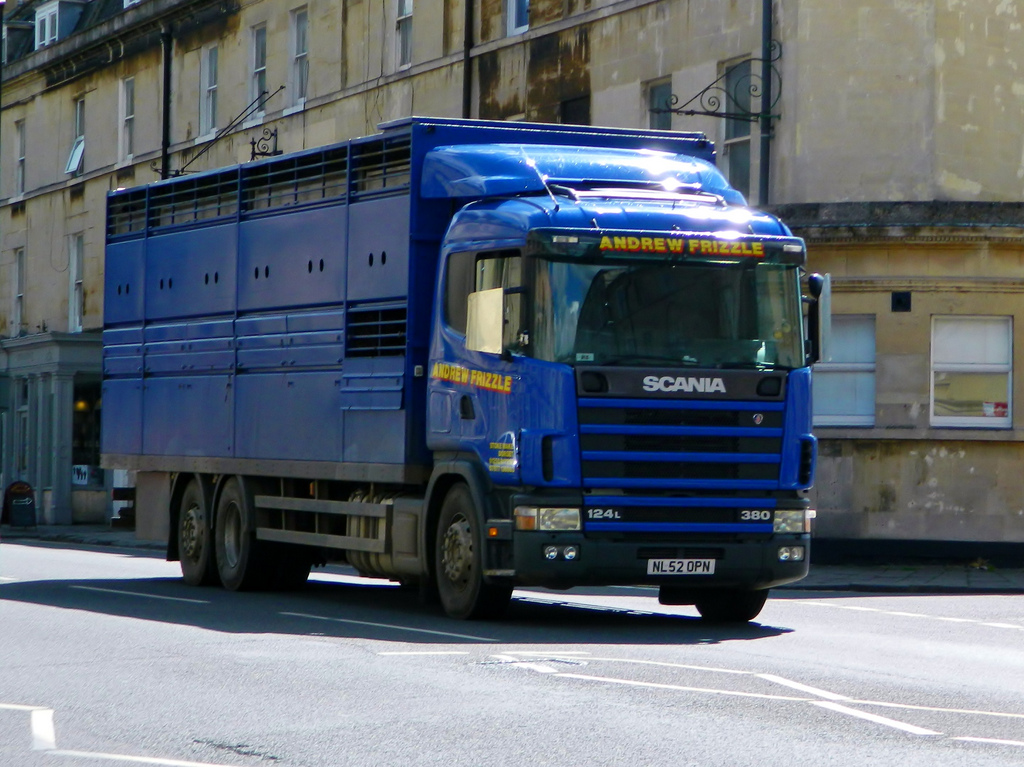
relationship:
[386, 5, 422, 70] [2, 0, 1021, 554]
white window on building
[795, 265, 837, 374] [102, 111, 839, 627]
mirror on truck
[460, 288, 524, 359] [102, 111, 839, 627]
mirror on truck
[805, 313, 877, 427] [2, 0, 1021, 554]
white window on building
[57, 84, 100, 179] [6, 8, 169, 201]
white window in building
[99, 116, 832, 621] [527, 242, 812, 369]
blue truck has window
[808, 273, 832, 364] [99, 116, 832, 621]
mirror on blue truck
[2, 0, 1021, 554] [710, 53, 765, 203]
building on window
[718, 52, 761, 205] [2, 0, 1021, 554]
window on building